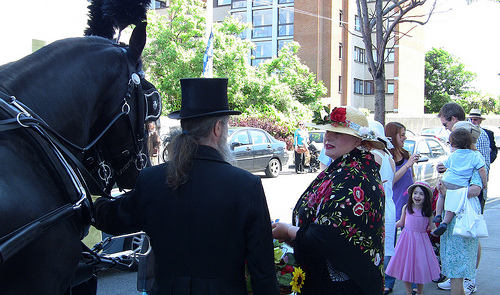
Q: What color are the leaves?
A: Green.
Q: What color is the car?
A: Black.